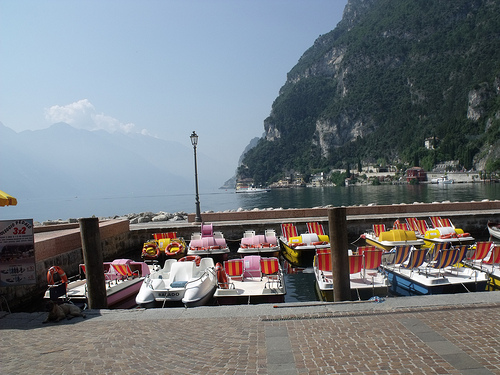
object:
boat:
[211, 255, 283, 304]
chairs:
[259, 256, 281, 281]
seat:
[385, 243, 412, 264]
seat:
[397, 245, 428, 274]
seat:
[425, 247, 458, 278]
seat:
[443, 243, 467, 274]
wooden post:
[326, 208, 353, 301]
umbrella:
[1, 189, 17, 209]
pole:
[79, 217, 107, 309]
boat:
[133, 255, 218, 307]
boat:
[311, 245, 389, 301]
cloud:
[44, 97, 156, 136]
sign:
[1, 218, 39, 311]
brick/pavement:
[0, 292, 500, 374]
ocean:
[0, 180, 500, 224]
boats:
[276, 220, 331, 267]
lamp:
[186, 130, 198, 149]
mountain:
[218, 1, 500, 188]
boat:
[236, 184, 271, 195]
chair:
[222, 259, 245, 282]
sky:
[1, 1, 349, 168]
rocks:
[153, 214, 168, 220]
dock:
[0, 200, 500, 373]